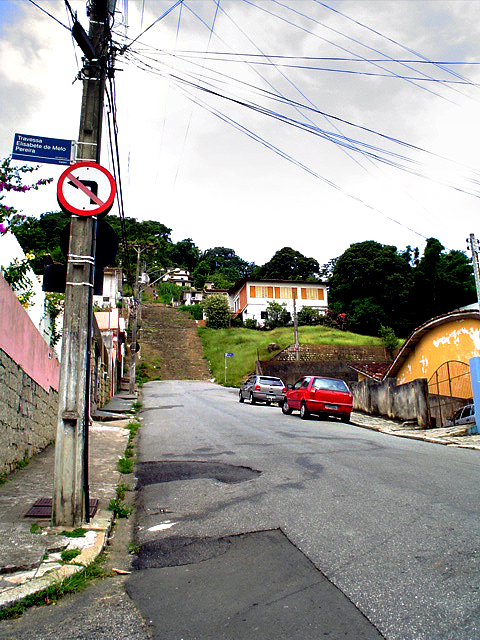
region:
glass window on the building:
[278, 285, 282, 294]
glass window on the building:
[283, 283, 288, 294]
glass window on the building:
[305, 284, 309, 296]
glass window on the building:
[310, 284, 314, 296]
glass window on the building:
[231, 298, 234, 310]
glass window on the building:
[233, 295, 236, 307]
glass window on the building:
[189, 290, 194, 295]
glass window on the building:
[180, 277, 188, 288]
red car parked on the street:
[279, 374, 355, 424]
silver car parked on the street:
[238, 374, 286, 405]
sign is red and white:
[55, 162, 116, 216]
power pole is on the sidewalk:
[0, 0, 120, 529]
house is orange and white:
[347, 295, 479, 400]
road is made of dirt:
[136, 300, 223, 380]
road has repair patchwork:
[118, 456, 390, 638]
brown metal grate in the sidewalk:
[19, 494, 100, 520]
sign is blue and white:
[7, 131, 75, 168]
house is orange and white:
[228, 275, 328, 329]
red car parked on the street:
[272, 373, 362, 421]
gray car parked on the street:
[231, 370, 284, 407]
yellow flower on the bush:
[18, 247, 38, 263]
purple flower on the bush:
[10, 177, 27, 193]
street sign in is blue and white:
[12, 129, 70, 168]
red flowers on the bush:
[334, 307, 346, 324]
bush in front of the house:
[199, 295, 230, 329]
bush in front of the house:
[159, 278, 187, 305]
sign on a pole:
[7, 125, 79, 169]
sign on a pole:
[58, 160, 128, 223]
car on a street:
[281, 366, 365, 423]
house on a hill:
[231, 257, 333, 324]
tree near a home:
[258, 240, 324, 281]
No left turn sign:
[55, 158, 121, 220]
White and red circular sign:
[55, 159, 115, 218]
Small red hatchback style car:
[278, 371, 356, 423]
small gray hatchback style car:
[239, 369, 287, 407]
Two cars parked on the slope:
[236, 371, 356, 425]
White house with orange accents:
[230, 272, 332, 326]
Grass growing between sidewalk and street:
[0, 555, 110, 627]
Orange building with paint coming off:
[380, 298, 478, 397]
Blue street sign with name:
[13, 128, 79, 165]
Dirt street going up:
[134, 279, 214, 384]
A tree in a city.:
[268, 302, 285, 325]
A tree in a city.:
[380, 326, 395, 350]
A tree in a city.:
[416, 244, 437, 269]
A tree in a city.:
[158, 275, 200, 305]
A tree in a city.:
[165, 234, 201, 267]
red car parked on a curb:
[280, 372, 352, 422]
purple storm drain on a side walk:
[92, 413, 111, 420]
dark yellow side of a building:
[394, 318, 478, 396]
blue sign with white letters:
[12, 130, 75, 164]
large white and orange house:
[230, 277, 328, 329]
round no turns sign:
[55, 162, 117, 218]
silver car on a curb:
[236, 374, 284, 404]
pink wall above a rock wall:
[1, 275, 59, 390]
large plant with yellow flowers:
[3, 241, 61, 289]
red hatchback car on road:
[270, 365, 357, 428]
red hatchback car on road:
[267, 372, 360, 429]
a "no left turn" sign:
[56, 163, 119, 215]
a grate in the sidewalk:
[24, 496, 96, 517]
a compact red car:
[282, 375, 354, 420]